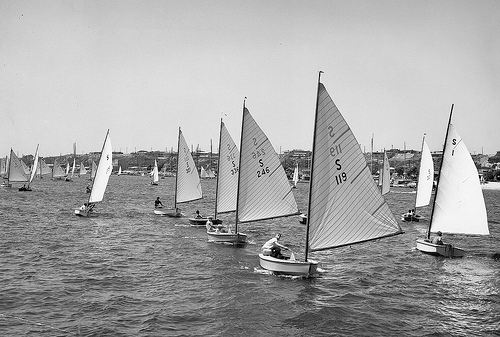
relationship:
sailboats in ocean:
[43, 142, 469, 256] [162, 294, 253, 323]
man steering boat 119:
[265, 232, 295, 257] [311, 90, 385, 307]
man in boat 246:
[203, 214, 225, 245] [238, 104, 287, 232]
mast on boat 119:
[311, 89, 319, 265] [256, 70, 404, 280]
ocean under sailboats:
[162, 294, 253, 323] [43, 142, 469, 256]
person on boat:
[154, 197, 174, 218] [157, 132, 201, 219]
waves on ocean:
[44, 243, 124, 318] [162, 294, 253, 323]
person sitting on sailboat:
[71, 200, 121, 226] [87, 133, 133, 220]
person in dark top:
[154, 197, 174, 218] [154, 202, 165, 204]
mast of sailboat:
[311, 89, 319, 265] [87, 133, 133, 220]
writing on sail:
[250, 144, 284, 182] [434, 107, 484, 254]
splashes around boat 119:
[251, 266, 283, 288] [256, 70, 404, 280]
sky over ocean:
[198, 28, 275, 59] [162, 294, 253, 323]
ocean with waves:
[162, 294, 253, 323] [44, 243, 124, 318]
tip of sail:
[310, 63, 325, 86] [434, 107, 484, 254]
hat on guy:
[431, 225, 446, 235] [431, 218, 447, 256]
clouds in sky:
[364, 39, 425, 63] [198, 28, 275, 59]